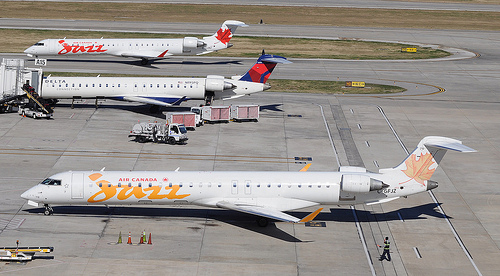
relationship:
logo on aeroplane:
[58, 40, 106, 55] [23, 19, 251, 58]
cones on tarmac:
[117, 229, 154, 246] [0, 94, 499, 274]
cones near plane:
[117, 229, 154, 246] [15, 135, 485, 232]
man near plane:
[372, 238, 400, 269] [18, 121, 482, 241]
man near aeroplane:
[138, 226, 147, 242] [39, 49, 295, 113]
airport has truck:
[0, 0, 498, 273] [132, 120, 187, 148]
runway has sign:
[1, 47, 438, 92] [344, 78, 365, 87]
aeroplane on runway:
[23, 19, 251, 58] [1, 49, 460, 98]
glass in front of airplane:
[42, 179, 61, 187] [17, 130, 477, 230]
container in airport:
[157, 109, 201, 131] [0, 0, 497, 275]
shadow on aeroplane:
[24, 199, 456, 245] [18, 133, 475, 243]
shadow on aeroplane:
[47, 96, 286, 120] [22, 46, 294, 112]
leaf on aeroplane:
[396, 143, 440, 185] [20, 135, 474, 225]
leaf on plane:
[216, 25, 233, 45] [24, 20, 244, 68]